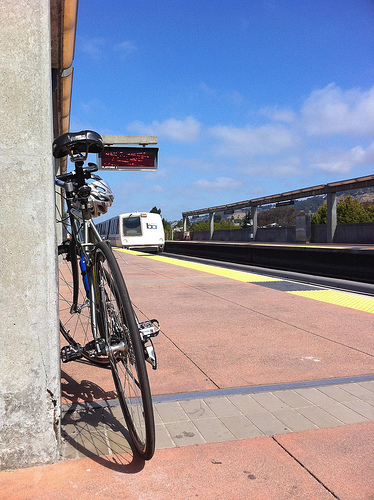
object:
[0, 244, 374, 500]
ground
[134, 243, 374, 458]
platform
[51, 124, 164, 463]
bike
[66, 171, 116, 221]
helmet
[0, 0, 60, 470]
wall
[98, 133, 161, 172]
sign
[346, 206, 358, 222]
trees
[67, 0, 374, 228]
sky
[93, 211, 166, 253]
stain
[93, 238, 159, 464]
tires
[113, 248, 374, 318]
stripe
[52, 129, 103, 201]
post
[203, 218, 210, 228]
bushes